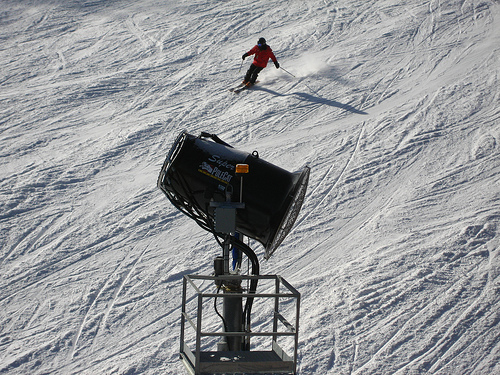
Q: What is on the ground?
A: The ground is covered in snow.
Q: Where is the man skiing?
A: He skis down a mountain.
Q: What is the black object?
A: A light.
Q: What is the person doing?
A: Skiing.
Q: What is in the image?
A: Public alarm system.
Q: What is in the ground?
A: Ice.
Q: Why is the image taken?
A: Remembrance.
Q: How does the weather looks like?
A: Interesting.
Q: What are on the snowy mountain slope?
A: Ski lines.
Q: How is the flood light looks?
A: Dark colored.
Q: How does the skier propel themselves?
A: Ski poles.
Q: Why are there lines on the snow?
A: From skis.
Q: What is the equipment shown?
A: Light.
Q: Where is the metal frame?
A: Under light.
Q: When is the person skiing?
A: Cold sunny day.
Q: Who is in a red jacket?
A: Skier.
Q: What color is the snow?
A: White.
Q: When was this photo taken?
A: During the day.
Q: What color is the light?
A: Black.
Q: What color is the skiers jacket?
A: Red.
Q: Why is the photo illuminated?
A: Sunlight.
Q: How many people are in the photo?
A: One.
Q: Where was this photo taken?
A: A ski resort.